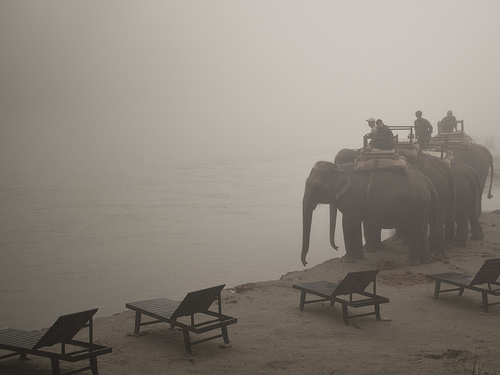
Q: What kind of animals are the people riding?
A: Elephants.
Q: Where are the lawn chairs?
A: On the dirt.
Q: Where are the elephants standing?
A: Near the shoreline.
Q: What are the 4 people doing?
A: Riding elephants.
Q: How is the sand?
A: Wet and brown.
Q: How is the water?
A: Still and gray.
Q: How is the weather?
A: Gray and foggy.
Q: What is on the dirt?
A: Chairs.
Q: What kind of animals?
A: Elephants.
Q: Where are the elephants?
A: On the shore.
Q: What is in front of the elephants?
A: The ocean.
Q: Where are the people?
A: On the elephants.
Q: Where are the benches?
A: On the beach.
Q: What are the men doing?
A: Riding the elephants.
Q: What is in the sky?
A: Fog.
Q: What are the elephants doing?
A: Standing.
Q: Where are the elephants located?
A: By the river.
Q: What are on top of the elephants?
A: Humans.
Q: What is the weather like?
A: Foggy.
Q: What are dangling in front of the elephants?
A: Trunks.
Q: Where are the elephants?
A: By the water.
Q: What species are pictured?
A: Elephants and humans.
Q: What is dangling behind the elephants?
A: Tails.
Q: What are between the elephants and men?
A: Pillows.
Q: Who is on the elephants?
A: People.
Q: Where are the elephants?
A: Next to cliff.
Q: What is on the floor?
A: Chairs.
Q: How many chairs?
A: 4.